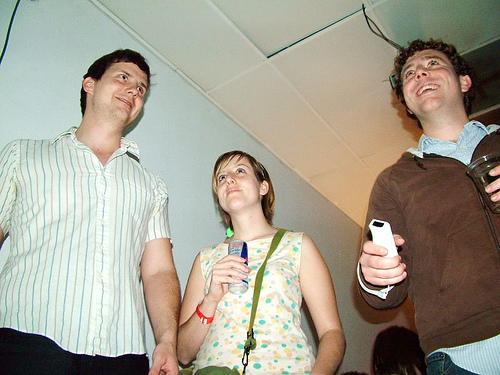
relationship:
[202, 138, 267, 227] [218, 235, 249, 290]
girl holding can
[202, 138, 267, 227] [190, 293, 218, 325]
girl wearing bracelet